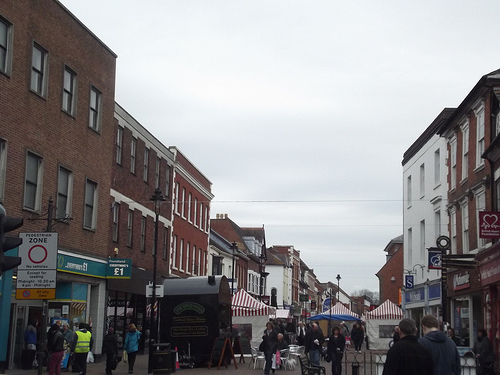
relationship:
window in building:
[85, 83, 105, 132] [2, 0, 119, 372]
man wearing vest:
[71, 320, 91, 374] [74, 329, 93, 357]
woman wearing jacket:
[123, 323, 143, 369] [126, 331, 138, 356]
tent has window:
[366, 299, 404, 321] [377, 323, 399, 339]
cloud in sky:
[210, 75, 324, 113] [62, 1, 499, 292]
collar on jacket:
[399, 334, 421, 344] [379, 332, 432, 374]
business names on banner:
[63, 259, 91, 272] [57, 250, 108, 278]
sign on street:
[165, 298, 213, 341] [152, 348, 374, 372]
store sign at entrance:
[447, 272, 469, 289] [448, 272, 479, 356]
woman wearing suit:
[325, 323, 347, 374] [330, 334, 345, 374]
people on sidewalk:
[22, 306, 141, 373] [4, 349, 152, 374]